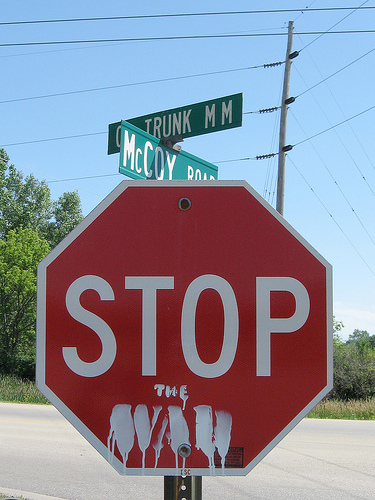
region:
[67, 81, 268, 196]
two street signs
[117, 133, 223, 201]
a street sign that says mccoy road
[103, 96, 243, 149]
a street sign that says trunk mm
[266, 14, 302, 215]
a tall silver pole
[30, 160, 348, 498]
a red stop rign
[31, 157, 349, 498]
a stop sign with graffiti on it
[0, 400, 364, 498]
an empty road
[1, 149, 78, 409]
tall trees in the distance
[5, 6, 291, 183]
some telephone wires above a road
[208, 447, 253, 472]
a small black square on a stop sign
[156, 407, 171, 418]
part of a sign post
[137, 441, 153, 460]
side of a post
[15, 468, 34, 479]
edge of a road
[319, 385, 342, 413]
side of a grass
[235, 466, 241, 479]
edge of a post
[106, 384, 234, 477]
white paint on a stop sign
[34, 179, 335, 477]
a red stop sign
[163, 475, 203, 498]
a metal pole with a stop sign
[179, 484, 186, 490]
a hole in a metal stop sign pole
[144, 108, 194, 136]
the word trunk on a green road sign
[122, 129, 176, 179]
the word McCoy on a green road sign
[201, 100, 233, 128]
two Ms on a road sign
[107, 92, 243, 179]
two signs above a stop sign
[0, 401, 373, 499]
a paved road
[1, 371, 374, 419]
green grass by a paved road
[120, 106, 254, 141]
Green street sign on top of pole.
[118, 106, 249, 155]
White lettering on green sign.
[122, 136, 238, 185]
Green street sign above stop sign.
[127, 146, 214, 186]
White lettering on green sign.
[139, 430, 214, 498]
Stop sign attached to dark pole.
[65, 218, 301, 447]
Large red sign attached to pole.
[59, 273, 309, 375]
White lettering on red sign.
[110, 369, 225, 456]
White wording under stop on sign.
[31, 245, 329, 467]
Sign has 8 sides.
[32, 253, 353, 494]
Sign has white outer edge.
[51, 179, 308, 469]
this is a stop sign.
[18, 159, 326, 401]
The sign is red.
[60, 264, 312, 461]
The sign says "stop the war".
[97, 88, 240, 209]
this is a cross street.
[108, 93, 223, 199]
The street signs are green.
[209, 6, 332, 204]
this is a power line.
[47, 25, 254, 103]
The sky is very blue.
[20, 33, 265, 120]
The weather looks very clear.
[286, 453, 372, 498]
The street is made of concrete.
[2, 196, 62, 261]
The tree is green.